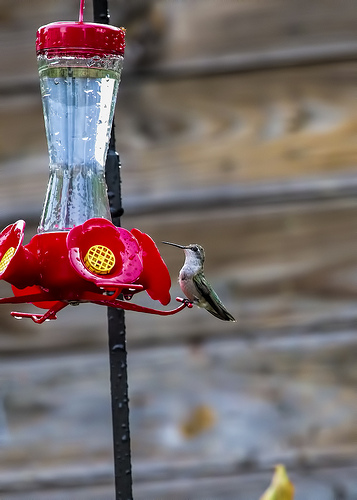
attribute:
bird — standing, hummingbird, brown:
[185, 223, 246, 329]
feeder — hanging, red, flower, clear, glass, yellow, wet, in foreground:
[2, 5, 204, 290]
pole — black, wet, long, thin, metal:
[101, 332, 139, 499]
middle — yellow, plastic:
[81, 245, 124, 273]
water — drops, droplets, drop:
[61, 144, 100, 209]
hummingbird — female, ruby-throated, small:
[172, 236, 240, 316]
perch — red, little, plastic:
[101, 303, 190, 315]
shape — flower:
[69, 225, 142, 288]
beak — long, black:
[153, 234, 190, 253]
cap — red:
[37, 21, 124, 66]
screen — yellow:
[90, 240, 118, 281]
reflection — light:
[91, 84, 108, 171]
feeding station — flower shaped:
[125, 225, 184, 313]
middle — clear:
[44, 68, 104, 226]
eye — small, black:
[192, 247, 197, 251]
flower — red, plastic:
[76, 216, 148, 292]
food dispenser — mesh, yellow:
[2, 242, 14, 274]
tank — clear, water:
[37, 68, 109, 223]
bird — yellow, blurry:
[256, 449, 297, 498]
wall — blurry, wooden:
[156, 54, 314, 196]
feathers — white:
[172, 261, 196, 286]